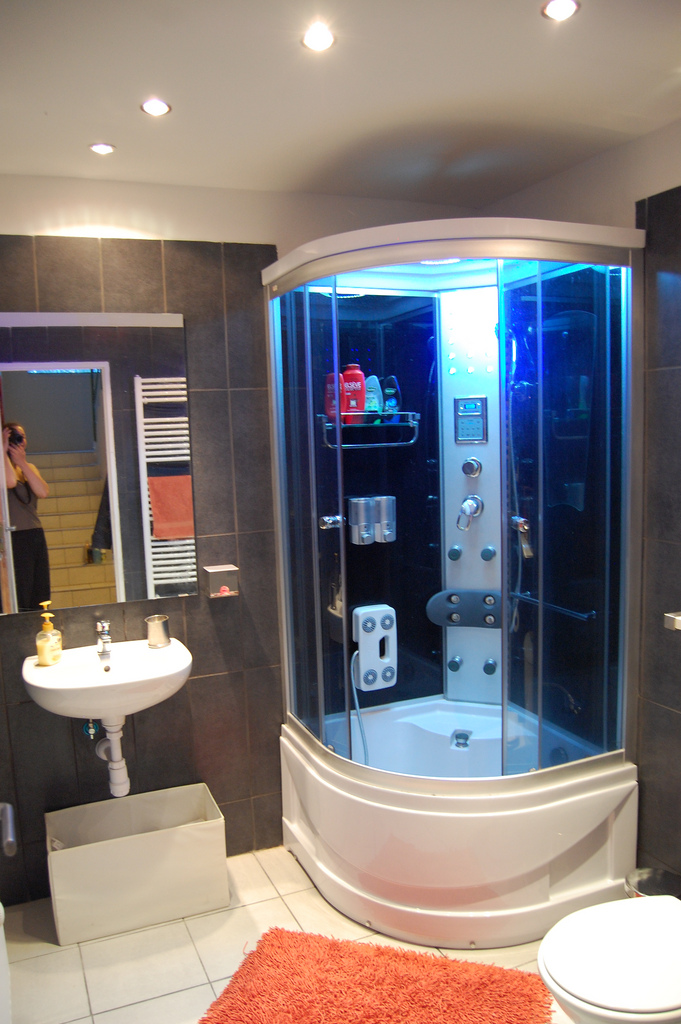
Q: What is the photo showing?
A: It is showing a bathroom.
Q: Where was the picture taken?
A: It was taken at the bathroom.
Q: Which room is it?
A: It is a bathroom.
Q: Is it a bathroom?
A: Yes, it is a bathroom.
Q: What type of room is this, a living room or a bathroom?
A: It is a bathroom.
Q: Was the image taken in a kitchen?
A: No, the picture was taken in a bathroom.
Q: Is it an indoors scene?
A: Yes, it is indoors.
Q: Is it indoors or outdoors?
A: It is indoors.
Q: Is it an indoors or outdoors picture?
A: It is indoors.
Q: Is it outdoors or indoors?
A: It is indoors.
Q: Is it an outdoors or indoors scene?
A: It is indoors.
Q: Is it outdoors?
A: No, it is indoors.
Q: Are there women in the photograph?
A: Yes, there is a woman.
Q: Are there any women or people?
A: Yes, there is a woman.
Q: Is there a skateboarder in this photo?
A: No, there are no skateboarders.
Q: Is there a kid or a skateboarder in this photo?
A: No, there are no skateboarders or children.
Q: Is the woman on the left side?
A: Yes, the woman is on the left of the image.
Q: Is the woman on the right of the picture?
A: No, the woman is on the left of the image.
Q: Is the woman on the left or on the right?
A: The woman is on the left of the image.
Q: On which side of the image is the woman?
A: The woman is on the left of the image.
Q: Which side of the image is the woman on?
A: The woman is on the left of the image.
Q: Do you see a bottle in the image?
A: Yes, there is a bottle.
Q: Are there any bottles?
A: Yes, there is a bottle.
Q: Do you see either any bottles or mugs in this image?
A: Yes, there is a bottle.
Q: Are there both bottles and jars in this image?
A: No, there is a bottle but no jars.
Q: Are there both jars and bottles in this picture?
A: No, there is a bottle but no jars.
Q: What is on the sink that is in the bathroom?
A: The bottle is on the sink.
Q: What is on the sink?
A: The bottle is on the sink.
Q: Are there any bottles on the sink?
A: Yes, there is a bottle on the sink.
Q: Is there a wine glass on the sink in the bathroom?
A: No, there is a bottle on the sink.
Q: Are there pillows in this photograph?
A: No, there are no pillows.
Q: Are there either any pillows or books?
A: No, there are no pillows or books.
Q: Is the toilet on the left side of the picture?
A: No, the toilet is on the right of the image.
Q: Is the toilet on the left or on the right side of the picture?
A: The toilet is on the right of the image.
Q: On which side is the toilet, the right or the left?
A: The toilet is on the right of the image.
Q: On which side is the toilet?
A: The toilet is on the right of the image.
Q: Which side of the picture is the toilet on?
A: The toilet is on the right of the image.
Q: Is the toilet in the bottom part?
A: Yes, the toilet is in the bottom of the image.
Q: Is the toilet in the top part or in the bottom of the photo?
A: The toilet is in the bottom of the image.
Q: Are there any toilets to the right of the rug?
A: Yes, there is a toilet to the right of the rug.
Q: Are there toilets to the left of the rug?
A: No, the toilet is to the right of the rug.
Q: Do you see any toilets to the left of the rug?
A: No, the toilet is to the right of the rug.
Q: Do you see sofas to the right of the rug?
A: No, there is a toilet to the right of the rug.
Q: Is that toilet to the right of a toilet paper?
A: No, the toilet is to the right of a rug.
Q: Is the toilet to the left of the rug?
A: No, the toilet is to the right of the rug.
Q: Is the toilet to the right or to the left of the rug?
A: The toilet is to the right of the rug.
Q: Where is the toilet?
A: The toilet is in the bathroom.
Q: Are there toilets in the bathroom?
A: Yes, there is a toilet in the bathroom.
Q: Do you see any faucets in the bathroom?
A: No, there is a toilet in the bathroom.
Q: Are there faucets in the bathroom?
A: No, there is a toilet in the bathroom.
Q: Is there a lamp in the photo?
A: No, there are no lamps.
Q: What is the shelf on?
A: The shelf is on the wall.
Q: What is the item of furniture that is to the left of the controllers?
A: The piece of furniture is a shelf.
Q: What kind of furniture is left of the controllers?
A: The piece of furniture is a shelf.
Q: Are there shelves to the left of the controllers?
A: Yes, there is a shelf to the left of the controllers.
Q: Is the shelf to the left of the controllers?
A: Yes, the shelf is to the left of the controllers.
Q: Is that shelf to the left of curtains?
A: No, the shelf is to the left of the controllers.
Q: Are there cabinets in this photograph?
A: No, there are no cabinets.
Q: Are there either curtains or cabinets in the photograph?
A: No, there are no cabinets or curtains.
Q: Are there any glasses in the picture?
A: No, there are no glasses.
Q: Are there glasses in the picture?
A: No, there are no glasses.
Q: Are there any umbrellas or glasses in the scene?
A: No, there are no glasses or umbrellas.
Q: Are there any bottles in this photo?
A: Yes, there is a bottle.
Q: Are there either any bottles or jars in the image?
A: Yes, there is a bottle.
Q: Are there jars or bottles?
A: Yes, there is a bottle.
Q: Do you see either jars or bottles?
A: Yes, there is a bottle.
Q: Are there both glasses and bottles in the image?
A: No, there is a bottle but no glasses.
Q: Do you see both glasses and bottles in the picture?
A: No, there is a bottle but no glasses.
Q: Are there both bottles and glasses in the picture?
A: No, there is a bottle but no glasses.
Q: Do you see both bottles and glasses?
A: No, there is a bottle but no glasses.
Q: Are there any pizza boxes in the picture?
A: No, there are no pizza boxes.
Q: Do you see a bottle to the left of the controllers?
A: Yes, there is a bottle to the left of the controllers.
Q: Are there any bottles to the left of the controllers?
A: Yes, there is a bottle to the left of the controllers.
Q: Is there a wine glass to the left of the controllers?
A: No, there is a bottle to the left of the controllers.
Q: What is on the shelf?
A: The bottle is on the shelf.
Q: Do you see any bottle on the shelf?
A: Yes, there is a bottle on the shelf.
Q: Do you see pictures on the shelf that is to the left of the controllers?
A: No, there is a bottle on the shelf.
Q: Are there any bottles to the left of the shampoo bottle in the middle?
A: Yes, there is a bottle to the left of the shampoo bottle.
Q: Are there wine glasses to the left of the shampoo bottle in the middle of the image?
A: No, there is a bottle to the left of the shampoo bottle.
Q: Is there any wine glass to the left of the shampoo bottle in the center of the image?
A: No, there is a bottle to the left of the shampoo bottle.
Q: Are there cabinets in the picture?
A: No, there are no cabinets.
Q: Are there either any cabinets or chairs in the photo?
A: No, there are no cabinets or chairs.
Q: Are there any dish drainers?
A: No, there are no dish drainers.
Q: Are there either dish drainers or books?
A: No, there are no dish drainers or books.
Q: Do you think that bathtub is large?
A: Yes, the bathtub is large.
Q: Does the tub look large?
A: Yes, the tub is large.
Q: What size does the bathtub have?
A: The bathtub has large size.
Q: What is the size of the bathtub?
A: The bathtub is large.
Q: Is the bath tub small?
A: No, the bath tub is large.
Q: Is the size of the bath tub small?
A: No, the bath tub is large.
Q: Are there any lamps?
A: No, there are no lamps.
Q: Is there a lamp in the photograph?
A: No, there are no lamps.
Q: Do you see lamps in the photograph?
A: No, there are no lamps.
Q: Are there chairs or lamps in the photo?
A: No, there are no lamps or chairs.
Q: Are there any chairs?
A: No, there are no chairs.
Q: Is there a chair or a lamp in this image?
A: No, there are no chairs or lamps.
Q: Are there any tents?
A: No, there are no tents.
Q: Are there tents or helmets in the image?
A: No, there are no tents or helmets.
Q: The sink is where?
A: The sink is in the bathroom.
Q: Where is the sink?
A: The sink is in the bathroom.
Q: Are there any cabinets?
A: No, there are no cabinets.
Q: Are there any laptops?
A: No, there are no laptops.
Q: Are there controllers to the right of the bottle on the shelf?
A: Yes, there are controllers to the right of the bottle.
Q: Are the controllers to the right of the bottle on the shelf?
A: Yes, the controllers are to the right of the bottle.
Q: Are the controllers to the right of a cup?
A: No, the controllers are to the right of the bottle.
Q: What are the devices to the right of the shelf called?
A: The devices are controllers.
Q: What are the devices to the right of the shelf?
A: The devices are controllers.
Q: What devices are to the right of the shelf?
A: The devices are controllers.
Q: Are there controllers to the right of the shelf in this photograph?
A: Yes, there are controllers to the right of the shelf.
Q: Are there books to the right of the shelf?
A: No, there are controllers to the right of the shelf.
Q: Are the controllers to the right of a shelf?
A: Yes, the controllers are to the right of a shelf.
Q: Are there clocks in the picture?
A: No, there are no clocks.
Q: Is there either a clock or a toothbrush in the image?
A: No, there are no clocks or toothbrushes.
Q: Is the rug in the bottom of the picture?
A: Yes, the rug is in the bottom of the image.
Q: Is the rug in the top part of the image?
A: No, the rug is in the bottom of the image.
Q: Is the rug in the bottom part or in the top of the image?
A: The rug is in the bottom of the image.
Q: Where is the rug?
A: The rug is on the floor.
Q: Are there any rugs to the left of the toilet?
A: Yes, there is a rug to the left of the toilet.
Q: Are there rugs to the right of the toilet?
A: No, the rug is to the left of the toilet.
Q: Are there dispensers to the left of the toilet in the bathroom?
A: No, there is a rug to the left of the toilet.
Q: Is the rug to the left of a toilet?
A: Yes, the rug is to the left of a toilet.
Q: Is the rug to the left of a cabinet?
A: No, the rug is to the left of a toilet.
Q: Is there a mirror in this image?
A: Yes, there is a mirror.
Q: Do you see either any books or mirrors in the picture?
A: Yes, there is a mirror.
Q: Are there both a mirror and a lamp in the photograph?
A: No, there is a mirror but no lamps.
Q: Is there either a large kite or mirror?
A: Yes, there is a large mirror.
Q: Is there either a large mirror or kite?
A: Yes, there is a large mirror.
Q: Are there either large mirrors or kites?
A: Yes, there is a large mirror.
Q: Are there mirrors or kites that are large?
A: Yes, the mirror is large.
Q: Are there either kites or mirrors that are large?
A: Yes, the mirror is large.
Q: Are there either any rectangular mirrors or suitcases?
A: Yes, there is a rectangular mirror.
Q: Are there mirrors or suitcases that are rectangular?
A: Yes, the mirror is rectangular.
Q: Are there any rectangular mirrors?
A: Yes, there is a rectangular mirror.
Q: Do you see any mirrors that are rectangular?
A: Yes, there is a mirror that is rectangular.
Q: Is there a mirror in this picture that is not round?
A: Yes, there is a rectangular mirror.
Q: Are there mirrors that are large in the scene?
A: Yes, there is a large mirror.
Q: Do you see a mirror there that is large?
A: Yes, there is a mirror that is large.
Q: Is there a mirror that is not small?
A: Yes, there is a large mirror.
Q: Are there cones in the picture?
A: No, there are no cones.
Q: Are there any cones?
A: No, there are no cones.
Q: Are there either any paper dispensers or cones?
A: No, there are no cones or paper dispensers.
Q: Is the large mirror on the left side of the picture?
A: Yes, the mirror is on the left of the image.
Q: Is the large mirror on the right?
A: No, the mirror is on the left of the image.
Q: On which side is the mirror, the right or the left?
A: The mirror is on the left of the image.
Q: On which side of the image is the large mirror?
A: The mirror is on the left of the image.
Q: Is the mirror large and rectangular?
A: Yes, the mirror is large and rectangular.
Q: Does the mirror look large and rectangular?
A: Yes, the mirror is large and rectangular.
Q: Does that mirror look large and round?
A: No, the mirror is large but rectangular.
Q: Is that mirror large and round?
A: No, the mirror is large but rectangular.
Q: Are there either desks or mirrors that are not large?
A: No, there is a mirror but it is large.